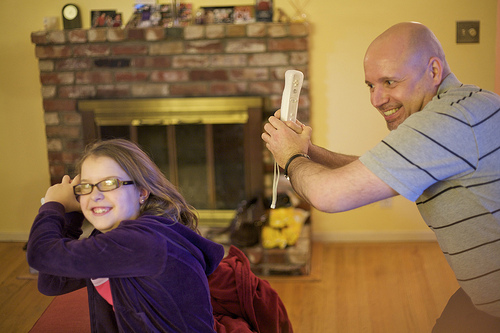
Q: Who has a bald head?
A: Man holding controller.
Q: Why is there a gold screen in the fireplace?
A: Prevent sparks flying.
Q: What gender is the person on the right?
A: Male.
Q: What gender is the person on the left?
A: Female.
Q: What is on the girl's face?
A: Glasses.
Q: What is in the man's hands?
A: Wii remote.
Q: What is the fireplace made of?
A: Brick.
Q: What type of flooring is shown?
A: Hardwood.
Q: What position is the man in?
A: Standing.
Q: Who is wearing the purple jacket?
A: Girl.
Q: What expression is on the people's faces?
A: Smiles.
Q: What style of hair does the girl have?
A: Long.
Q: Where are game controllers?
A: In people's hands.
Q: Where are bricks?
A: On a fireplace.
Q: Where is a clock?
A: On fireplace mantle.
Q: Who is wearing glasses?
A: A girl.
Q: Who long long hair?
A: A girl.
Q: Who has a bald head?
A: The man.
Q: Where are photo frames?
A: On the fireplace mantle.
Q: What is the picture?
A: Father and daughter.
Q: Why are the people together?
A: Playing.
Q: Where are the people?
A: Living room.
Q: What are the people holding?
A: Game remotes.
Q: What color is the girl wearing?
A: Purple.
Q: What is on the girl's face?
A: Glasses.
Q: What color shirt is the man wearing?
A: Gray.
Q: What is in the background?
A: Fireplace.